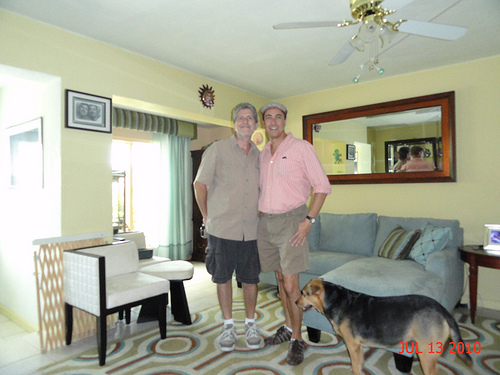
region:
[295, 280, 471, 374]
The dog is over the carpet.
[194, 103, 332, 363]
Two men are stand up.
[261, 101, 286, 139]
A man has a gray hat.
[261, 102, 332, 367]
The man is wearing a pink shirt and beige shorts.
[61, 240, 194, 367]
The chair is color white.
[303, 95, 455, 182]
The mirror is on the wall.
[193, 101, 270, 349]
The old man is wearing a beige shirt and gray shorts.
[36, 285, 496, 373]
The carpet in the floor is colorful.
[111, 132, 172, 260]
There is a window in the living room.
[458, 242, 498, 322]
The round table is beside to the sofa.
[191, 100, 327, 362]
two men posing for a picture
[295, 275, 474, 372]
a dog standing near the two men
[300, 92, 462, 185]
large rectangular mirror hanging on the wall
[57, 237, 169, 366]
white chair with black legs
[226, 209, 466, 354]
gray-colored sofa behind two men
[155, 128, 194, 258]
blue curtain on a window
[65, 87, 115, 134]
picture in a black frame hanging on the wall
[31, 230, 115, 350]
a baby gate behind the white chair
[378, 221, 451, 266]
pillows displayed on the sofa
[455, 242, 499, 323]
round brown table next to the sofa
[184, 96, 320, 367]
two men posing for photo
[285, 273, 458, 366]
black and tan dog next to men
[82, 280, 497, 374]
patterned area rug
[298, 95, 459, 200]
mirror with wood frame on wall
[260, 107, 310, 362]
man wearing pink shirt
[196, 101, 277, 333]
man wearing tan shirt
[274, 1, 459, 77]
white and gold ceiling fan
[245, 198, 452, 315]
gray couch behind men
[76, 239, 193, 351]
white and black chair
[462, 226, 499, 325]
wood table beside gray couch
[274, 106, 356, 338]
man standing in room in pink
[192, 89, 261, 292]
man standing in room in beige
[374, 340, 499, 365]
photo date on lower right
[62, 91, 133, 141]
rectangle picture on wall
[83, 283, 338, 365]
large carpet under men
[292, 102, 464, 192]
rectangle mirror on wall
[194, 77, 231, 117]
small round ornament on wall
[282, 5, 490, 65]
white ceiling fan over men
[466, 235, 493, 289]
wooden table by couch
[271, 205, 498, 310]
gray couch by wall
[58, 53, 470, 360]
two guys and a dog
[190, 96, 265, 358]
a man in black shorts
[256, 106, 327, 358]
a man in a pink shirt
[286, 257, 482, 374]
a dog in the living room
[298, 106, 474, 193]
a mirror on the wall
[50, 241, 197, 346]
a white chair and stool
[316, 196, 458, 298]
a grey couch in the living room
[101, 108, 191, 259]
a window in the home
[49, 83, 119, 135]
a picture on the wall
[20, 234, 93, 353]
a gate behind the chair